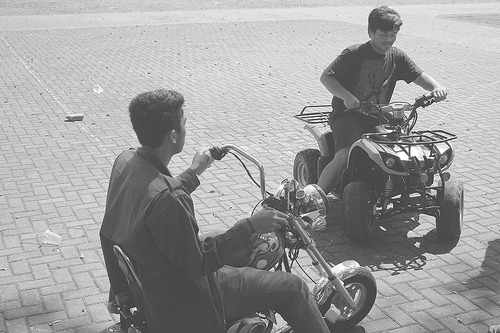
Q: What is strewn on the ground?
A: Trash.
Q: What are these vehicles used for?
A: Recreation.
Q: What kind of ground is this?
A: Brick.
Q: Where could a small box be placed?
A: Back rack.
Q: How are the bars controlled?
A: By hand.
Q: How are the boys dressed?
A: Casually.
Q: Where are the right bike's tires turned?
A: Left.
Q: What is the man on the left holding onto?
A: The handlebars.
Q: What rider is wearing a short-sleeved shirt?
A: Rider on the right.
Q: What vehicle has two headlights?
A: Vehicle on the right.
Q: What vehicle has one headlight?
A: Vehicle on the left.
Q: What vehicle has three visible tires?
A: Vehicle on the right.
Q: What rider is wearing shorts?
A: Rider on the right.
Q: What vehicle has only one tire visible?
A: Vehicle on the left.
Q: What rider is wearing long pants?
A: Rider on the left.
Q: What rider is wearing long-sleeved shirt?
A: Rider on the left.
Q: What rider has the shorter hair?
A: Rider on the left.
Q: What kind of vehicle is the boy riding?
A: An ATV.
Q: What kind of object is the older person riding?
A: A low rider bike.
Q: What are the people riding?
A: Motor vehicles.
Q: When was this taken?
A: Daytime.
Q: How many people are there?
A: 2.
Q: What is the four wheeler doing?
A: Turning right.